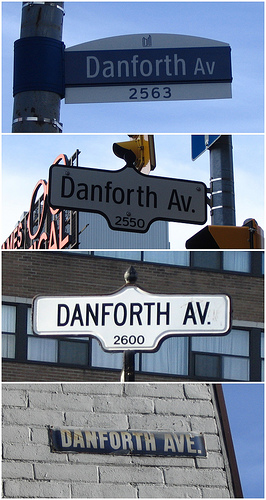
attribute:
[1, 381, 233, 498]
wall — white, brick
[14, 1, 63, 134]
post — gray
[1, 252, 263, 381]
building — brick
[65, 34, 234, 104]
sign — blue, curved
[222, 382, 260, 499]
sky — blue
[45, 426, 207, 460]
sign — black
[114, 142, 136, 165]
light — green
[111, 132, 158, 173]
traffic light — yellow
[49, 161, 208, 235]
sign — white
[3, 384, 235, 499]
building — brickk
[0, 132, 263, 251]
sky — blue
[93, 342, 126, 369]
curtain — white